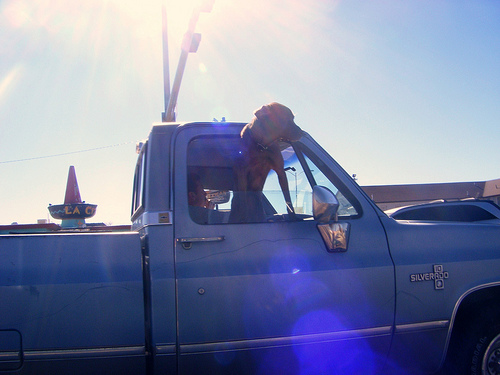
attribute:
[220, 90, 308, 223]
dog — brown, looking, sticking, large, tan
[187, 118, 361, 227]
window — bluish, glass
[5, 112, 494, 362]
truck — blue, pickup, old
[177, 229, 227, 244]
handle — silver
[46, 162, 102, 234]
sign — mexican, restaurant, hat, sombrero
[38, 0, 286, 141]
sun — shining, bright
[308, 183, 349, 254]
mirror — silver, side view, rear view, chrome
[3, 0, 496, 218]
sky — blue, bright, cloudless, cloudy, clear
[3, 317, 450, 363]
stripe — silver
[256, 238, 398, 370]
circles — flare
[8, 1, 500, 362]
photo — outdoors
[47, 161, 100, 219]
hat — mexican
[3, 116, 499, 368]
side — passenger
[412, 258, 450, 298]
logo — silverado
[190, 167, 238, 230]
driver — looking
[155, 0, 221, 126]
signal — traffic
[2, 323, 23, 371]
tank — gas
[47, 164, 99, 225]
sombrero — mexican, black, red, yellow, blue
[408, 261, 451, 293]
plate — silver, small, silverado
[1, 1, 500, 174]
sunshine — bright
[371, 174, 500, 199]
roof — brown